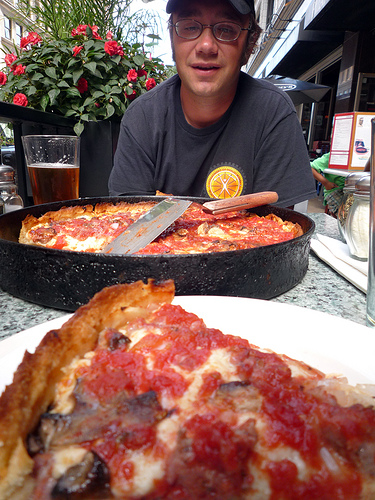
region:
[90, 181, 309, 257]
pizza slicer in the middle of the pan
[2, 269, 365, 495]
slice of pizza in a plate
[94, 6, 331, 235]
person wearing spectacles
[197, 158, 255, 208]
logo on a black t shirt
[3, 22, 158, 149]
flowered plant in the background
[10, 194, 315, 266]
entire pizza in a pan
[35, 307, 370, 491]
cheesy part of the pizza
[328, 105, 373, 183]
menu of the restaurant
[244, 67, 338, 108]
shade for people to sit under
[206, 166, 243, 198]
orange logo on the front of a shirt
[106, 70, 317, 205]
black men's tee shirt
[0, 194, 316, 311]
cast iron skillet with food on it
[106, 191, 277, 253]
serving utensil sitting on the food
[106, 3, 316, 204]
man looking at food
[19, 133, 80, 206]
glass of beer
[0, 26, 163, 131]
bush with red flowers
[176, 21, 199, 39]
left glasses lense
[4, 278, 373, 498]
slice of casserole on a plate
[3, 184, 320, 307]
A Large Deep Dish Pepperoni Pizza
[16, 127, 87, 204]
A nice cold glass of beer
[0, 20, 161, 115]
A nice pot of beautiful carnations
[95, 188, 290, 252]
a large spatula made of metal and wood.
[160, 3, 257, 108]
A hungry man wearing glasses.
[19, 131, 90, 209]
The beer is amber colored.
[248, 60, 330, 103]
The umbrella is blue.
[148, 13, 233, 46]
glasses on the man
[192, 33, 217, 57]
nose of the man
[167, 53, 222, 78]
mouth of the man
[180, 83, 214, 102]
chin of the man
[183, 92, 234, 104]
neck of the man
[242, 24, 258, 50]
ear of the man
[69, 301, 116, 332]
crust of the pizza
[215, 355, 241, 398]
cheese on the pizza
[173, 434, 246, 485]
sauce on the pizza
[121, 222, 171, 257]
Pizza cutter in the pan with pizza.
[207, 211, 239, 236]
Pizza cutter in the pan with pizza.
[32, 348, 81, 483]
Pizza cutter in the pan with pizza.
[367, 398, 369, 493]
Pizza cutter in the pan with pizza.